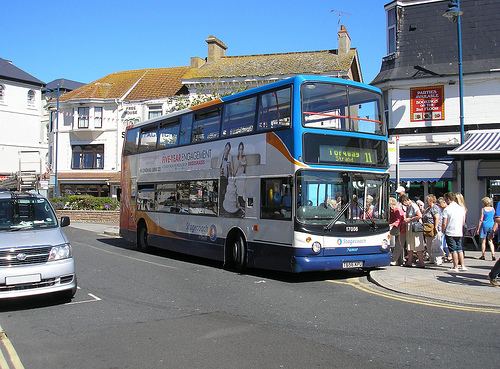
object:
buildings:
[0, 25, 365, 203]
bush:
[49, 193, 120, 211]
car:
[0, 190, 77, 299]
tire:
[230, 233, 247, 272]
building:
[368, 0, 500, 236]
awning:
[447, 127, 500, 155]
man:
[442, 192, 467, 272]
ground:
[0, 209, 500, 369]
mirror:
[61, 216, 70, 226]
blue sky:
[0, 0, 388, 86]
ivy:
[168, 76, 268, 110]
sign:
[410, 85, 445, 122]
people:
[389, 191, 469, 273]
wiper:
[323, 202, 352, 230]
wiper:
[357, 202, 379, 231]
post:
[456, 0, 464, 144]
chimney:
[205, 34, 228, 63]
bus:
[118, 75, 390, 274]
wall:
[188, 86, 234, 96]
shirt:
[442, 202, 466, 238]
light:
[312, 242, 321, 253]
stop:
[390, 233, 474, 273]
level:
[124, 74, 381, 131]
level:
[118, 168, 391, 273]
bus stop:
[365, 227, 500, 284]